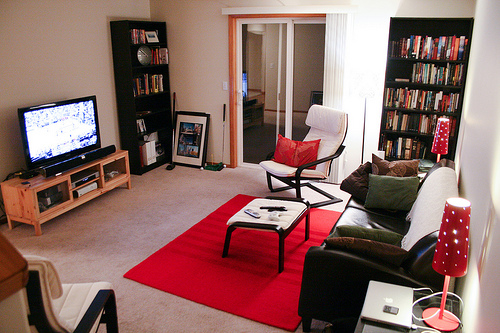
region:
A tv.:
[8, 83, 113, 173]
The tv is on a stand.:
[2, 87, 139, 242]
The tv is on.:
[4, 85, 111, 175]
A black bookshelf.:
[95, 8, 197, 180]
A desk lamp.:
[413, 185, 473, 331]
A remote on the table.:
[232, 201, 267, 230]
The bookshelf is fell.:
[376, 11, 471, 170]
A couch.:
[293, 155, 455, 330]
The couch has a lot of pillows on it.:
[296, 156, 463, 330]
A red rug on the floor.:
[116, 187, 338, 330]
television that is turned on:
[17, 97, 101, 171]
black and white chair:
[262, 102, 346, 202]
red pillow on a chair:
[272, 132, 317, 168]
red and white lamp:
[420, 201, 472, 331]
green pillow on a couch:
[363, 172, 416, 214]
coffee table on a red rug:
[219, 194, 311, 276]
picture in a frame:
[168, 109, 210, 172]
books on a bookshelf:
[385, 82, 463, 137]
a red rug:
[122, 193, 341, 331]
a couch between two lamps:
[297, 156, 461, 325]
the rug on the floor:
[141, 176, 317, 328]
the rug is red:
[135, 219, 235, 324]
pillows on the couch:
[327, 147, 429, 274]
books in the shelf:
[378, 23, 468, 181]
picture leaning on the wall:
[158, 96, 224, 198]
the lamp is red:
[406, 184, 466, 330]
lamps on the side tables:
[420, 91, 477, 329]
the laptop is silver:
[346, 272, 409, 331]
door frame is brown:
[221, 15, 250, 180]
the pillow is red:
[273, 123, 331, 176]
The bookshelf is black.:
[100, 9, 190, 177]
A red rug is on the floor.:
[117, 186, 354, 331]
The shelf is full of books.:
[373, 13, 479, 180]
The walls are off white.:
[184, 20, 216, 81]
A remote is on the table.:
[236, 202, 271, 229]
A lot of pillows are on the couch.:
[297, 145, 475, 322]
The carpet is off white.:
[96, 217, 145, 249]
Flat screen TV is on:
[15, 90, 120, 164]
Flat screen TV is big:
[21, 89, 126, 174]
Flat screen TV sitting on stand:
[6, 87, 131, 230]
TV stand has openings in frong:
[0, 142, 162, 229]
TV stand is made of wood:
[5, 150, 157, 225]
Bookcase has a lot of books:
[106, 15, 186, 173]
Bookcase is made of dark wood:
[106, 15, 188, 190]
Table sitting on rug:
[145, 180, 342, 329]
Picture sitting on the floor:
[170, 99, 214, 175]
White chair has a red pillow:
[261, 92, 363, 211]